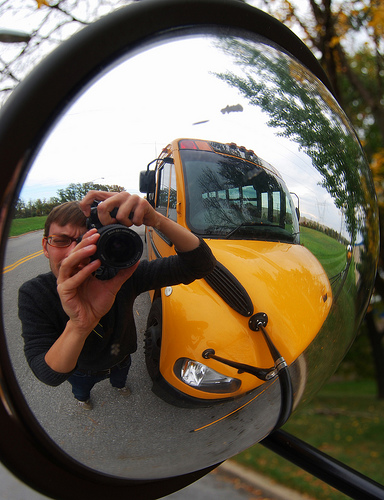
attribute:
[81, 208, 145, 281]
camera — black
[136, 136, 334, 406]
bus — school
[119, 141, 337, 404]
bus — yellow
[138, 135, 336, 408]
school bus — big, yellow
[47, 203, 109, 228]
hair — brown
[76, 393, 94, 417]
shoe — brown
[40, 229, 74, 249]
glasses — brown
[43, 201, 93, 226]
hair — brown